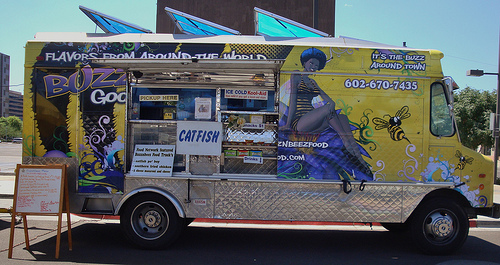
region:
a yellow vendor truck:
[12, 36, 498, 236]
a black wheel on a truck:
[412, 193, 472, 257]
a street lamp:
[465, 62, 499, 191]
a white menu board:
[5, 155, 75, 261]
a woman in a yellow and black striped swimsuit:
[282, 42, 377, 171]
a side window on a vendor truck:
[418, 79, 459, 152]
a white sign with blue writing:
[171, 118, 229, 155]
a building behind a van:
[1, 46, 22, 136]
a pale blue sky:
[1, 1, 498, 86]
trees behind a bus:
[450, 86, 497, 161]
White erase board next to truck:
[7, 160, 74, 260]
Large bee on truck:
[369, 105, 417, 149]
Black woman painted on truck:
[280, 47, 372, 175]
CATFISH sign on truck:
[172, 115, 222, 160]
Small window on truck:
[425, 79, 460, 138]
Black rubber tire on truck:
[115, 192, 182, 250]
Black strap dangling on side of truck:
[338, 174, 355, 201]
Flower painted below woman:
[278, 94, 378, 181]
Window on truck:
[132, 83, 216, 120]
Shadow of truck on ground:
[25, 215, 497, 263]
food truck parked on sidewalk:
[9, 9, 498, 257]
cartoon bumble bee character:
[365, 102, 419, 154]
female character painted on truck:
[286, 47, 381, 182]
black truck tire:
[404, 187, 483, 264]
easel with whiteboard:
[4, 145, 76, 259]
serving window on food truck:
[87, 50, 288, 194]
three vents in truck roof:
[67, 5, 338, 47]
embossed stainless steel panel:
[197, 180, 406, 226]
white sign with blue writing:
[167, 113, 227, 166]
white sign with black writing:
[124, 135, 183, 180]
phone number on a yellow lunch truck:
[341, 75, 421, 91]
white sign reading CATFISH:
[176, 121, 223, 155]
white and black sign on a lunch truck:
[129, 145, 176, 175]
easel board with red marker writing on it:
[8, 160, 78, 260]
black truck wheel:
[119, 192, 184, 252]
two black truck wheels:
[111, 188, 478, 258]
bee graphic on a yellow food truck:
[366, 99, 419, 146]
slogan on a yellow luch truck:
[361, 49, 431, 74]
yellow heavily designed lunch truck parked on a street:
[22, 8, 499, 253]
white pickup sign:
[138, 95, 183, 101]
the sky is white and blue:
[389, 30, 436, 67]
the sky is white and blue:
[343, 7, 484, 144]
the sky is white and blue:
[363, 11, 454, 88]